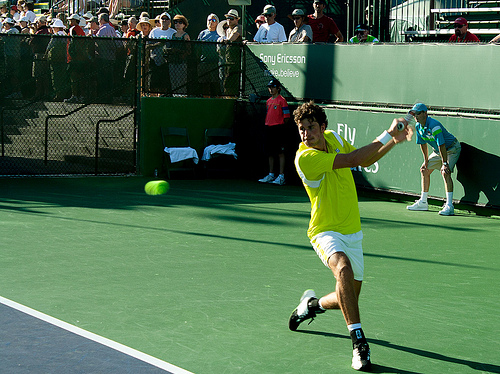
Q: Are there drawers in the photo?
A: No, there are no drawers.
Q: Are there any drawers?
A: No, there are no drawers.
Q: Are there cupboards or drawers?
A: No, there are no drawers or cupboards.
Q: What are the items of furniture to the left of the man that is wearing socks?
A: The pieces of furniture are chairs.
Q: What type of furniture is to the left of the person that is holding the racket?
A: The pieces of furniture are chairs.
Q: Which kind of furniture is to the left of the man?
A: The pieces of furniture are chairs.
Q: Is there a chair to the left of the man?
A: Yes, there are chairs to the left of the man.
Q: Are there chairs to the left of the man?
A: Yes, there are chairs to the left of the man.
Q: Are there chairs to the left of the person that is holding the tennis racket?
A: Yes, there are chairs to the left of the man.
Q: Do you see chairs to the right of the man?
A: No, the chairs are to the left of the man.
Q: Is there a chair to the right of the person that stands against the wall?
A: No, the chairs are to the left of the man.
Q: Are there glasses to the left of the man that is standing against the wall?
A: No, there are chairs to the left of the man.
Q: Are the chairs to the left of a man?
A: Yes, the chairs are to the left of a man.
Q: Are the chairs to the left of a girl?
A: No, the chairs are to the left of a man.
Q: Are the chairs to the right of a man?
A: No, the chairs are to the left of a man.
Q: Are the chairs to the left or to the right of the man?
A: The chairs are to the left of the man.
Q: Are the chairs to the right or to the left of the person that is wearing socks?
A: The chairs are to the left of the man.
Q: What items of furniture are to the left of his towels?
A: The pieces of furniture are chairs.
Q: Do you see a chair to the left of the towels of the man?
A: Yes, there are chairs to the left of the towels.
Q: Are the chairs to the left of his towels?
A: Yes, the chairs are to the left of the towels.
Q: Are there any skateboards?
A: No, there are no skateboards.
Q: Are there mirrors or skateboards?
A: No, there are no skateboards or mirrors.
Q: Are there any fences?
A: Yes, there is a fence.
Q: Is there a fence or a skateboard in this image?
A: Yes, there is a fence.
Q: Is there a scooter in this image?
A: No, there are no scooters.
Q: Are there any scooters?
A: No, there are no scooters.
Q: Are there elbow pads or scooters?
A: No, there are no scooters or elbow pads.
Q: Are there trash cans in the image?
A: No, there are no trash cans.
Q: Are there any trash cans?
A: No, there are no trash cans.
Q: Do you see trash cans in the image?
A: No, there are no trash cans.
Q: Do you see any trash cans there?
A: No, there are no trash cans.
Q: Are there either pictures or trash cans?
A: No, there are no trash cans or pictures.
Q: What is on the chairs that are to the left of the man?
A: The towels are on the chairs.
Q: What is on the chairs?
A: The towels are on the chairs.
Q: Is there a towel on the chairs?
A: Yes, there are towels on the chairs.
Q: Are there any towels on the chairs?
A: Yes, there are towels on the chairs.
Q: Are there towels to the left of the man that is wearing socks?
A: Yes, there are towels to the left of the man.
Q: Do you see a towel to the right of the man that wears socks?
A: No, the towels are to the left of the man.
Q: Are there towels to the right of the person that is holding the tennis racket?
A: No, the towels are to the left of the man.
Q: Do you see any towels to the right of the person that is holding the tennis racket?
A: No, the towels are to the left of the man.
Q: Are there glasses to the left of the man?
A: No, there are towels to the left of the man.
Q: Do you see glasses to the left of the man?
A: No, there are towels to the left of the man.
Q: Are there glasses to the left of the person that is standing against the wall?
A: No, there are towels to the left of the man.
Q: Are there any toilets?
A: No, there are no toilets.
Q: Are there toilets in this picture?
A: No, there are no toilets.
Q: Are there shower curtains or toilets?
A: No, there are no toilets or shower curtains.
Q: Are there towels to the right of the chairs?
A: Yes, there are towels to the right of the chairs.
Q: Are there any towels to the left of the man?
A: Yes, there are towels to the left of the man.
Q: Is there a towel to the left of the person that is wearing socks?
A: Yes, there are towels to the left of the man.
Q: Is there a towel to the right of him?
A: No, the towels are to the left of the man.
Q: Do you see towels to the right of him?
A: No, the towels are to the left of the man.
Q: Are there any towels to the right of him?
A: No, the towels are to the left of the man.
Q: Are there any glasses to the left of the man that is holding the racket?
A: No, there are towels to the left of the man.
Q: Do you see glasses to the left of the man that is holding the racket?
A: No, there are towels to the left of the man.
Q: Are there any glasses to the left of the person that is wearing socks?
A: No, there are towels to the left of the man.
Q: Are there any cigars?
A: No, there are no cigars.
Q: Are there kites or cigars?
A: No, there are no cigars or kites.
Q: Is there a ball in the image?
A: Yes, there is a ball.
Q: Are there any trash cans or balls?
A: Yes, there is a ball.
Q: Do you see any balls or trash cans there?
A: Yes, there is a ball.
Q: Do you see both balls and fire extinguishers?
A: No, there is a ball but no fire extinguishers.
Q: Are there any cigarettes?
A: No, there are no cigarettes.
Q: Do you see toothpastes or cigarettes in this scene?
A: No, there are no cigarettes or toothpastes.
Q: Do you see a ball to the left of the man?
A: Yes, there is a ball to the left of the man.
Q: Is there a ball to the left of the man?
A: Yes, there is a ball to the left of the man.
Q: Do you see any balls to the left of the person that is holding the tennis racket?
A: Yes, there is a ball to the left of the man.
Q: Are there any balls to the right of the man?
A: No, the ball is to the left of the man.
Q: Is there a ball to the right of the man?
A: No, the ball is to the left of the man.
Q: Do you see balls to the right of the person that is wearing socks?
A: No, the ball is to the left of the man.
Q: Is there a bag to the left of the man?
A: No, there is a ball to the left of the man.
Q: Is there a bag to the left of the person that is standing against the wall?
A: No, there is a ball to the left of the man.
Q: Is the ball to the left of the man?
A: Yes, the ball is to the left of the man.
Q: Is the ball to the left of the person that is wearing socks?
A: Yes, the ball is to the left of the man.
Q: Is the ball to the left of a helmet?
A: No, the ball is to the left of the man.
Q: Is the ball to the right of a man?
A: No, the ball is to the left of a man.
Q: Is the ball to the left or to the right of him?
A: The ball is to the left of the man.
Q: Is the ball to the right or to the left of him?
A: The ball is to the left of the man.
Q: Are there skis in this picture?
A: No, there are no skis.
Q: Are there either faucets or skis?
A: No, there are no skis or faucets.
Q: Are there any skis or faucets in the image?
A: No, there are no skis or faucets.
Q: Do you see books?
A: No, there are no books.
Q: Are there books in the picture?
A: No, there are no books.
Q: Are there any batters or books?
A: No, there are no books or batters.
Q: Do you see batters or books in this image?
A: No, there are no books or batters.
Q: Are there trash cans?
A: No, there are no trash cans.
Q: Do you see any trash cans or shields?
A: No, there are no trash cans or shields.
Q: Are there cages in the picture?
A: No, there are no cages.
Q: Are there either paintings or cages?
A: No, there are no cages or paintings.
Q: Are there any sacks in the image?
A: No, there are no sacks.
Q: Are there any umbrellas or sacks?
A: No, there are no sacks or umbrellas.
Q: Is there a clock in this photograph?
A: No, there are no clocks.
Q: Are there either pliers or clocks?
A: No, there are no clocks or pliers.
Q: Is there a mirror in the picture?
A: No, there are no mirrors.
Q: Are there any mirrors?
A: No, there are no mirrors.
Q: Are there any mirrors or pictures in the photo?
A: No, there are no mirrors or pictures.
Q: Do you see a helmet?
A: No, there are no helmets.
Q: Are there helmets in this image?
A: No, there are no helmets.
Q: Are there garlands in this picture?
A: No, there are no garlands.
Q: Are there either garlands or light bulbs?
A: No, there are no garlands or light bulbs.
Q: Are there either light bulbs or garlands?
A: No, there are no garlands or light bulbs.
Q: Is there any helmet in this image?
A: No, there are no helmets.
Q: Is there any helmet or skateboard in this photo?
A: No, there are no helmets or skateboards.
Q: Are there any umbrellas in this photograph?
A: No, there are no umbrellas.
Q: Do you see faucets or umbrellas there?
A: No, there are no umbrellas or faucets.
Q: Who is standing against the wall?
A: The man is standing against the wall.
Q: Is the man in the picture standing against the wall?
A: Yes, the man is standing against the wall.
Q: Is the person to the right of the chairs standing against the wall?
A: Yes, the man is standing against the wall.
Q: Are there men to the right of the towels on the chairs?
A: Yes, there is a man to the right of the towels.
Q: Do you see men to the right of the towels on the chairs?
A: Yes, there is a man to the right of the towels.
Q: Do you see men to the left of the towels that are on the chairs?
A: No, the man is to the right of the towels.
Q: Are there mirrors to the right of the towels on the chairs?
A: No, there is a man to the right of the towels.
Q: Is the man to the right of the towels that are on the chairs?
A: Yes, the man is to the right of the towels.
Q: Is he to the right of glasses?
A: No, the man is to the right of the towels.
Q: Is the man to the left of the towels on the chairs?
A: No, the man is to the right of the towels.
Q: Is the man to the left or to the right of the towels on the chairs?
A: The man is to the right of the towels.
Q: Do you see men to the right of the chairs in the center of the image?
A: Yes, there is a man to the right of the chairs.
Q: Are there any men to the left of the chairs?
A: No, the man is to the right of the chairs.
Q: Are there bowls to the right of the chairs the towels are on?
A: No, there is a man to the right of the chairs.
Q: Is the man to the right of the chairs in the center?
A: Yes, the man is to the right of the chairs.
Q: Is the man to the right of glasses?
A: No, the man is to the right of the chairs.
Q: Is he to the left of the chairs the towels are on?
A: No, the man is to the right of the chairs.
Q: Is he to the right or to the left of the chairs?
A: The man is to the right of the chairs.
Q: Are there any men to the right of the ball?
A: Yes, there is a man to the right of the ball.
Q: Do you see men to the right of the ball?
A: Yes, there is a man to the right of the ball.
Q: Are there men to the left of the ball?
A: No, the man is to the right of the ball.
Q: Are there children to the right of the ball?
A: No, there is a man to the right of the ball.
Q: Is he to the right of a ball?
A: Yes, the man is to the right of a ball.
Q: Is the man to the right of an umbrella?
A: No, the man is to the right of a ball.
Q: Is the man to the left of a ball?
A: No, the man is to the right of a ball.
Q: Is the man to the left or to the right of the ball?
A: The man is to the right of the ball.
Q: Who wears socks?
A: The man wears socks.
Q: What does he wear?
A: The man wears socks.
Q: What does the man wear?
A: The man wears socks.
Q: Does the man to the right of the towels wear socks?
A: Yes, the man wears socks.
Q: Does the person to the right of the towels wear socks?
A: Yes, the man wears socks.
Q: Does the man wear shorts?
A: No, the man wears socks.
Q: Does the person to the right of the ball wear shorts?
A: No, the man wears socks.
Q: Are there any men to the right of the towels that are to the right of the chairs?
A: Yes, there is a man to the right of the towels.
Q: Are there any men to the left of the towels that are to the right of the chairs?
A: No, the man is to the right of the towels.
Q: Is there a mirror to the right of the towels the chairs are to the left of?
A: No, there is a man to the right of the towels.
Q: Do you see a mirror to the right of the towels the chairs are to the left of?
A: No, there is a man to the right of the towels.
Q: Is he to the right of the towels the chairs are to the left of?
A: Yes, the man is to the right of the towels.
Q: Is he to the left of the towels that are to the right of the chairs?
A: No, the man is to the right of the towels.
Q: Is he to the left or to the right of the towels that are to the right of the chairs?
A: The man is to the right of the towels.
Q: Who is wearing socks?
A: The man is wearing socks.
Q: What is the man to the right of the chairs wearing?
A: The man is wearing socks.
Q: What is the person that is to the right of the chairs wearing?
A: The man is wearing socks.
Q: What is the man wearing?
A: The man is wearing socks.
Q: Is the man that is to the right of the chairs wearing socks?
A: Yes, the man is wearing socks.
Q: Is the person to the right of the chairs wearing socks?
A: Yes, the man is wearing socks.